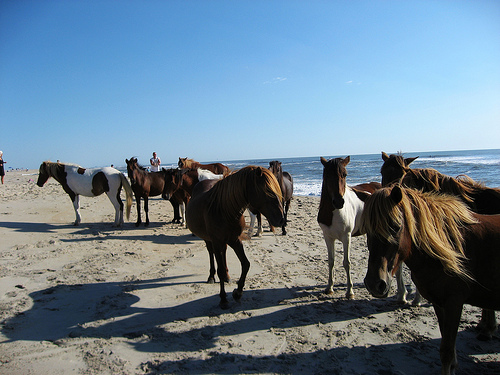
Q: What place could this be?
A: It is a beach.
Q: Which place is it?
A: It is a beach.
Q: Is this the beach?
A: Yes, it is the beach.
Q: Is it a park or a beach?
A: It is a beach.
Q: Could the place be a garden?
A: No, it is a beach.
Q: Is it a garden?
A: No, it is a beach.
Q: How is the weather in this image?
A: It is cloudless.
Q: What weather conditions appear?
A: It is cloudless.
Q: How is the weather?
A: It is cloudless.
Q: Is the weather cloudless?
A: Yes, it is cloudless.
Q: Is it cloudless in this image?
A: Yes, it is cloudless.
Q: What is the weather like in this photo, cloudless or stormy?
A: It is cloudless.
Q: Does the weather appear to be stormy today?
A: No, it is cloudless.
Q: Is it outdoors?
A: Yes, it is outdoors.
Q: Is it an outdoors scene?
A: Yes, it is outdoors.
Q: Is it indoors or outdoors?
A: It is outdoors.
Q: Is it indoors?
A: No, it is outdoors.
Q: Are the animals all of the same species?
A: Yes, all the animals are horses.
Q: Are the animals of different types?
A: No, all the animals are horses.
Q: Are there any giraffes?
A: No, there are no giraffes.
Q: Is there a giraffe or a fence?
A: No, there are no giraffes or fences.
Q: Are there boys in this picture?
A: No, there are no boys.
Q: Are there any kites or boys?
A: No, there are no boys or kites.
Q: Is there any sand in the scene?
A: Yes, there is sand.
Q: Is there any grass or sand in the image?
A: Yes, there is sand.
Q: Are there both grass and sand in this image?
A: No, there is sand but no grass.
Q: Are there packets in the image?
A: No, there are no packets.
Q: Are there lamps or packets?
A: No, there are no packets or lamps.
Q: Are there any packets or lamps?
A: No, there are no packets or lamps.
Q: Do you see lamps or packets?
A: No, there are no packets or lamps.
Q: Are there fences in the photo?
A: No, there are no fences.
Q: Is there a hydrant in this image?
A: No, there are no fire hydrants.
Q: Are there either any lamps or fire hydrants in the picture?
A: No, there are no fire hydrants or lamps.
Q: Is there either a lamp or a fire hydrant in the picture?
A: No, there are no fire hydrants or lamps.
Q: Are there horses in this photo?
A: Yes, there is a horse.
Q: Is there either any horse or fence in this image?
A: Yes, there is a horse.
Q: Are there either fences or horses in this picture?
A: Yes, there is a horse.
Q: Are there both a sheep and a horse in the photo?
A: No, there is a horse but no sheep.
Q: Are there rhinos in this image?
A: No, there are no rhinos.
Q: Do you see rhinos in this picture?
A: No, there are no rhinos.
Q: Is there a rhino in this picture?
A: No, there are no rhinos.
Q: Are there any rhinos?
A: No, there are no rhinos.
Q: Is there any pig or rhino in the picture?
A: No, there are no rhinos or pigs.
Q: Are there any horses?
A: Yes, there is a horse.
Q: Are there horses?
A: Yes, there is a horse.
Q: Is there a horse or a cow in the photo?
A: Yes, there is a horse.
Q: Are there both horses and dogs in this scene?
A: No, there is a horse but no dogs.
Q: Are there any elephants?
A: No, there are no elephants.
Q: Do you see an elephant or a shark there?
A: No, there are no elephants or sharks.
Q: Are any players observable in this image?
A: No, there are no players.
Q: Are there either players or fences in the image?
A: No, there are no players or fences.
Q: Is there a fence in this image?
A: No, there are no fences.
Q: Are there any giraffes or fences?
A: No, there are no fences or giraffes.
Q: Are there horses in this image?
A: Yes, there is a horse.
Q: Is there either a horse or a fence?
A: Yes, there is a horse.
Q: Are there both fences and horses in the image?
A: No, there is a horse but no fences.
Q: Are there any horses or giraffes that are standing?
A: Yes, the horse is standing.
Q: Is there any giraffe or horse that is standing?
A: Yes, the horse is standing.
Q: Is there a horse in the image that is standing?
A: Yes, there is a horse that is standing.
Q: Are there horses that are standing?
A: Yes, there is a horse that is standing.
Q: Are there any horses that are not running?
A: Yes, there is a horse that is standing.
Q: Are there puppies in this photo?
A: No, there are no puppies.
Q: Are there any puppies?
A: No, there are no puppies.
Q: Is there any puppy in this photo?
A: No, there are no puppies.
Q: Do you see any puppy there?
A: No, there are no puppies.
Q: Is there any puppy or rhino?
A: No, there are no puppies or rhinos.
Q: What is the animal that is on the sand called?
A: The animal is a horse.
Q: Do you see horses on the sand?
A: Yes, there is a horse on the sand.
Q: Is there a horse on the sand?
A: Yes, there is a horse on the sand.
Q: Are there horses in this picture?
A: Yes, there is a horse.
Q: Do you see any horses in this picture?
A: Yes, there is a horse.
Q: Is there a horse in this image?
A: Yes, there is a horse.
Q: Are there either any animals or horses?
A: Yes, there is a horse.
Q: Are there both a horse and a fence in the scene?
A: No, there is a horse but no fences.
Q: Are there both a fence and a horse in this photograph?
A: No, there is a horse but no fences.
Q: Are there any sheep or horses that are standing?
A: Yes, the horse is standing.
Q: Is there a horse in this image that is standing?
A: Yes, there is a horse that is standing.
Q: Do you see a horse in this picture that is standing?
A: Yes, there is a horse that is standing.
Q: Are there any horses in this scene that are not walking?
A: Yes, there is a horse that is standing.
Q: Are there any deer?
A: No, there are no deer.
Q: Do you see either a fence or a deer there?
A: No, there are no deer or fences.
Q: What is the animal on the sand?
A: The animal is a horse.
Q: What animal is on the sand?
A: The animal is a horse.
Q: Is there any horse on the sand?
A: Yes, there is a horse on the sand.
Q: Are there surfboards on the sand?
A: No, there is a horse on the sand.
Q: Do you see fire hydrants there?
A: No, there are no fire hydrants.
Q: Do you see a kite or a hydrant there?
A: No, there are no fire hydrants or kites.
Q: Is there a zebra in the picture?
A: No, there are no zebras.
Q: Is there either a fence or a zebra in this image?
A: No, there are no zebras or fences.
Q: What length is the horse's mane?
A: The mane is long.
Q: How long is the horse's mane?
A: The mane is long.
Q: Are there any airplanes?
A: No, there are no airplanes.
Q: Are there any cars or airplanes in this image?
A: No, there are no airplanes or cars.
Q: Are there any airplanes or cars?
A: No, there are no airplanes or cars.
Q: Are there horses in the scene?
A: Yes, there is a horse.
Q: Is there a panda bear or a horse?
A: Yes, there is a horse.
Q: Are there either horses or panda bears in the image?
A: Yes, there is a horse.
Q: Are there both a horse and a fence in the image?
A: No, there is a horse but no fences.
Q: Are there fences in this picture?
A: No, there are no fences.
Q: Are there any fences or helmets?
A: No, there are no fences or helmets.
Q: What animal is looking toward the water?
A: The horse is looking toward the water.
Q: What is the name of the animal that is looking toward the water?
A: The animal is a horse.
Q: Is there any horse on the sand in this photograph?
A: Yes, there is a horse on the sand.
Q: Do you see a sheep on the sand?
A: No, there is a horse on the sand.